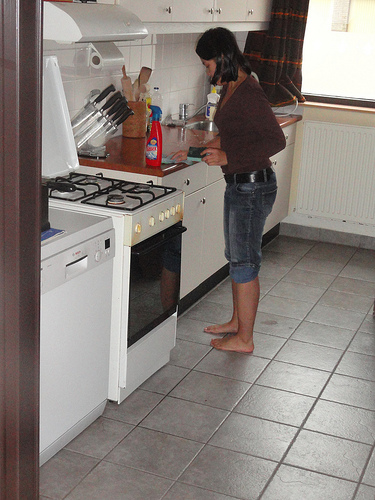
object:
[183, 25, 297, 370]
girl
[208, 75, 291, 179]
shirt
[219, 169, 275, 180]
belt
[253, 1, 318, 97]
curtain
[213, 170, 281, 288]
jeans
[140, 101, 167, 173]
cleaner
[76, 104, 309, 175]
counter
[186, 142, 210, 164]
sponge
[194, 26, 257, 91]
hair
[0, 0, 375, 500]
kitchen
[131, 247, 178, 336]
black oven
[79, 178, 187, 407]
oven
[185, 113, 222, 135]
sink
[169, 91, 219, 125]
faucet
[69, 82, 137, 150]
knives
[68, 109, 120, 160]
holder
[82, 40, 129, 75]
paper towel holder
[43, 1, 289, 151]
wall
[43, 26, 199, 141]
kitchen wall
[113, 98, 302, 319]
cabinets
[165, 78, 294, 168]
knobs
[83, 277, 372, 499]
floor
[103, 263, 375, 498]
floor tiles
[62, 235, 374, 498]
grey grout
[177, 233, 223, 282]
white edge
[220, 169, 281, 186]
hips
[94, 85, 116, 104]
handles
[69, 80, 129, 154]
knife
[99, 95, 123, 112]
handle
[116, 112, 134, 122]
handle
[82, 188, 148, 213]
burner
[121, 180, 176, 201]
burner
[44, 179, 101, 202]
burner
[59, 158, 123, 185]
burner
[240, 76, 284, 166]
sleeves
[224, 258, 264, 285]
cuffs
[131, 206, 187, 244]
stains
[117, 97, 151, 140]
canister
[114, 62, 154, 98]
cooking utensils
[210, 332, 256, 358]
feet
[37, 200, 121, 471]
washing machine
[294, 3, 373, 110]
window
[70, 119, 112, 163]
knife block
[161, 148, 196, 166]
rag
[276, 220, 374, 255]
tiles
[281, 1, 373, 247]
wall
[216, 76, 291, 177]
sweater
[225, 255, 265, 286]
knees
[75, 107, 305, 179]
countertop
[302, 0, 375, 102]
another wall